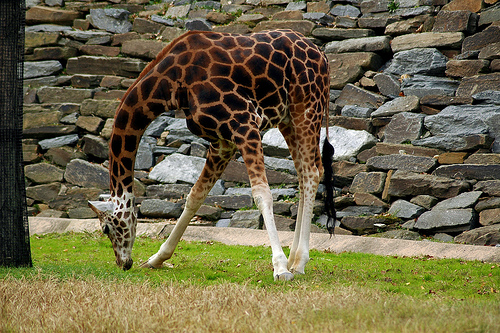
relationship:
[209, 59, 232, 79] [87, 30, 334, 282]
spot on giraffe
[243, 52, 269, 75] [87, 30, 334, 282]
spot on giraffe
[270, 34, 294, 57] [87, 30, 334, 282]
spot on giraffe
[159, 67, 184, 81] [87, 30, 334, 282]
spot on giraffe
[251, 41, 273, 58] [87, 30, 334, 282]
spot on giraffe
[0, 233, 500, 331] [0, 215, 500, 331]
grass on ground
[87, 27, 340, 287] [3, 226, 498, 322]
animal on grass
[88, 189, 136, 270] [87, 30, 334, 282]
head on giraffe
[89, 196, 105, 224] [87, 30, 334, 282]
ear part of giraffe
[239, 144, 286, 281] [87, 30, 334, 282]
front leg part of giraffe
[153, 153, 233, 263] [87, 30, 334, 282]
front leg part of giraffe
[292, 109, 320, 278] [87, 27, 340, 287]
leg part of animal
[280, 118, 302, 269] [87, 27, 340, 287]
leg part of animal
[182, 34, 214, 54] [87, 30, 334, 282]
spot on back of giraffe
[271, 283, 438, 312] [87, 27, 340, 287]
grass under animal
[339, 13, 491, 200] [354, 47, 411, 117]
wall made of rock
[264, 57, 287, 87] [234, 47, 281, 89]
spot on giraffe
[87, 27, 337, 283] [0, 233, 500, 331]
animal on grass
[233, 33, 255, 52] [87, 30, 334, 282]
spot on giraffe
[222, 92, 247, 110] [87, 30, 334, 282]
spot on giraffe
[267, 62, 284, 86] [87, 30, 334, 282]
spot on giraffe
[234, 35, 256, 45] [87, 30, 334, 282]
spot on giraffe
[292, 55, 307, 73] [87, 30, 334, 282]
spot on giraffe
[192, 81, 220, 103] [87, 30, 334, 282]
spot on giraffe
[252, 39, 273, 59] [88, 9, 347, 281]
spot on giraffe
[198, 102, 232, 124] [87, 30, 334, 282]
spot on giraffe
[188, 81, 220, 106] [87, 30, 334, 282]
spot on giraffe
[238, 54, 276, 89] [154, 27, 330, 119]
spot on a back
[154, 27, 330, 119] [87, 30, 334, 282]
back of a giraffe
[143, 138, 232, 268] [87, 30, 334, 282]
front leg of a giraffe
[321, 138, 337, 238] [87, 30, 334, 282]
tail of a giraffe